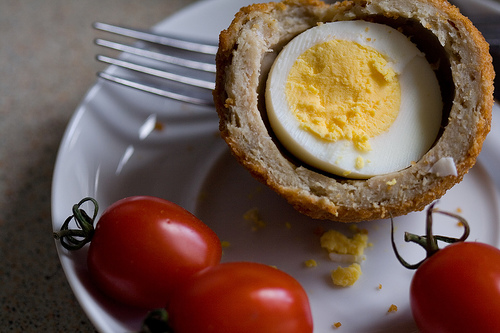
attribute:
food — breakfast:
[209, 1, 497, 226]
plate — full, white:
[46, 1, 498, 330]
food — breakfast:
[48, 193, 225, 315]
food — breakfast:
[134, 259, 314, 331]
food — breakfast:
[379, 202, 499, 329]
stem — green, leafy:
[387, 201, 469, 269]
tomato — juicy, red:
[56, 184, 228, 312]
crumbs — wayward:
[221, 202, 369, 292]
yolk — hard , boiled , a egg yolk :
[283, 36, 407, 145]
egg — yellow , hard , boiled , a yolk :
[274, 14, 458, 179]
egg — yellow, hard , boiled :
[262, 18, 444, 179]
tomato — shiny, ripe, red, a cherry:
[40, 174, 212, 289]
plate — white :
[43, 26, 490, 323]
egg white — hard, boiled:
[267, 17, 452, 182]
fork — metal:
[94, 19, 262, 124]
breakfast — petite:
[91, 3, 493, 328]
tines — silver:
[97, 71, 207, 103]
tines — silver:
[93, 35, 217, 70]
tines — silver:
[91, 19, 217, 53]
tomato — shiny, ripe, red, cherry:
[88, 192, 217, 312]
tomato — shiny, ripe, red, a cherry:
[162, 260, 312, 330]